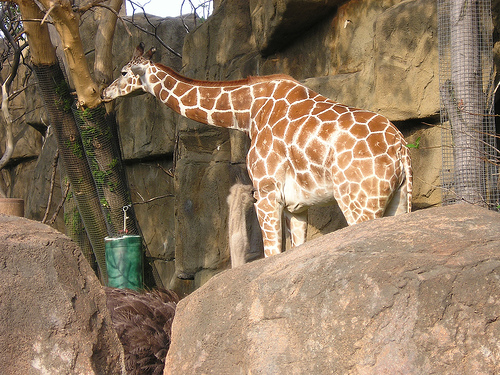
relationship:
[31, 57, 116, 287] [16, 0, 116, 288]
mesh on tree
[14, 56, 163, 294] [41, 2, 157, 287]
mesh on tree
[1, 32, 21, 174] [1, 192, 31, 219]
branch in planter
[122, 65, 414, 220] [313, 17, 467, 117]
girafee beside rock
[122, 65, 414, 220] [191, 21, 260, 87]
girafee beside rock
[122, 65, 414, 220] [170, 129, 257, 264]
girafee beside rock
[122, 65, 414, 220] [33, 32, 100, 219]
girafee beside rock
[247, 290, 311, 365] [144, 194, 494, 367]
highlights on boulder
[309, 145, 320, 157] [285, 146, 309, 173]
white spots on brown patch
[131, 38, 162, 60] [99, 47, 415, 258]
horns on girafee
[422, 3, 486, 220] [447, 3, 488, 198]
fencing on tree trunk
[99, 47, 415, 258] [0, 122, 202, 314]
girafee inside pen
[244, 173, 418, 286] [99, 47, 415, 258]
front feet on girafee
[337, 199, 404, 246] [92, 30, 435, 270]
feet on giraffe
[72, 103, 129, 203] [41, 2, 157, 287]
moss on tree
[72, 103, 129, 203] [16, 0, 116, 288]
moss on tree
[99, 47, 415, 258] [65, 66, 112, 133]
girafee eating leaves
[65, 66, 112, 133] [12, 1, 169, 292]
leaves on tree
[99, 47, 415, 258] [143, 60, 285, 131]
girafee bends neck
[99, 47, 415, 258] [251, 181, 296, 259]
girafee stands on front feet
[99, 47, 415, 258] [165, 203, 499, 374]
girafee behind boulder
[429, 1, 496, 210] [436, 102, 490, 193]
tree surrounded by mesh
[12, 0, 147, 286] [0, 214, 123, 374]
tree behind rock